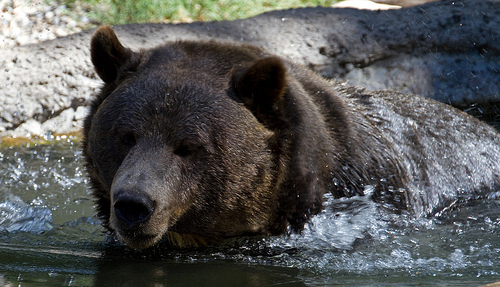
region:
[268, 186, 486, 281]
splashing water next the bear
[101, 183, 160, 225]
black nose of the bear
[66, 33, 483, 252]
brown bear in the water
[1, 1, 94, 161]
sunlight hitting the rocks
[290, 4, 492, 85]
grey rocks in shadow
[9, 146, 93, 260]
brown water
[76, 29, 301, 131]
ears of the bear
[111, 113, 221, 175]
black eyes of the bear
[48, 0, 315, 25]
green grass growing next to the pond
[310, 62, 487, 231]
wet fur of the bear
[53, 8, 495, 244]
a large brown bear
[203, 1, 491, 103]
a log in a river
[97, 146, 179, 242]
the nose of a brown bear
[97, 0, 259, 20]
grass on the bank of a river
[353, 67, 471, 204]
the wet fur of a bear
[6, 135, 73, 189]
drops of water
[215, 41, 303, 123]
a brown bears ear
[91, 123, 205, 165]
two eyes of a brown bear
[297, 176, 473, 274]
water being splashed by a bear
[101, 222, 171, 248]
a bears mouth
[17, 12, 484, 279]
bear out in the water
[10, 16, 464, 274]
big bear out in the water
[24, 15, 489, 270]
strong bear out in the water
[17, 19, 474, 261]
huge bear out in the water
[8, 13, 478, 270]
fierce bear out in the water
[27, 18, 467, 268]
ferocious bear out in the water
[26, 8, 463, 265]
impressive looking bear out in the water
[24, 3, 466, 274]
hungry bear out in the water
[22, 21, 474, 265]
mighty bear out in the water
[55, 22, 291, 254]
head of a bear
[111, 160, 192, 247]
bear has long snout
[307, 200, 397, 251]
water caps are white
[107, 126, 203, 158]
bears eyes are black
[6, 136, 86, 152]
there is ground by water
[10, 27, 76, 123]
there is snow on side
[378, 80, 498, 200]
bears body is wet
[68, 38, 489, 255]
there is a bear in water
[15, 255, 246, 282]
water is green and cool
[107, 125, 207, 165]
bear is sleeping in water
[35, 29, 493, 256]
bear is swimming in water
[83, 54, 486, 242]
One bear is in picture.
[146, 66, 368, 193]
Bear is black color.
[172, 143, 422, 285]
Bear is swimming in water.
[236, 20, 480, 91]
Logs are black color.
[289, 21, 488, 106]
Logs are behind the bear.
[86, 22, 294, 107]
Bear has two small ears.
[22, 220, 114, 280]
Water is green color.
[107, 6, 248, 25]
Grass is green color.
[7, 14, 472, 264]
Day time picture.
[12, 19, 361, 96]
Sunlight reflection is seen on logs.